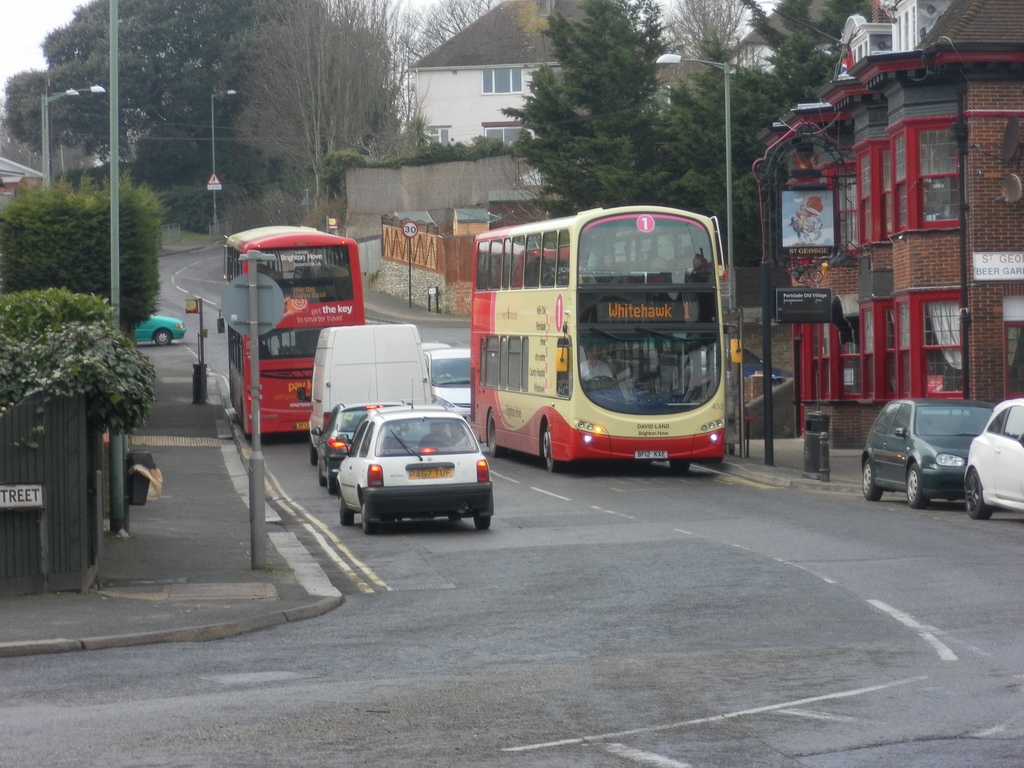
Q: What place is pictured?
A: It is a road.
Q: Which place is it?
A: It is a road.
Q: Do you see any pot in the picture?
A: No, there are no pots.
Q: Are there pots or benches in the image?
A: No, there are no pots or benches.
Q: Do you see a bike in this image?
A: No, there are no bikes.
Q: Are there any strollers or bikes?
A: No, there are no bikes or strollers.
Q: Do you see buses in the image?
A: Yes, there is a bus.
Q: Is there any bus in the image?
A: Yes, there is a bus.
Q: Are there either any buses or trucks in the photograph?
A: Yes, there is a bus.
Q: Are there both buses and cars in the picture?
A: Yes, there are both a bus and a car.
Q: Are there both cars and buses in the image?
A: Yes, there are both a bus and a car.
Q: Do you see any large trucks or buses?
A: Yes, there is a large bus.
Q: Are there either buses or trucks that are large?
A: Yes, the bus is large.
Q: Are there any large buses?
A: Yes, there is a large bus.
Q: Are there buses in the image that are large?
A: Yes, there is a bus that is large.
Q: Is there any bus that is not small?
A: Yes, there is a large bus.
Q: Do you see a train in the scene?
A: No, there are no trains.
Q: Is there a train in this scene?
A: No, there are no trains.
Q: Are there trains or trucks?
A: No, there are no trains or trucks.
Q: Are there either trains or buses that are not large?
A: No, there is a bus but it is large.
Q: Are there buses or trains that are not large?
A: No, there is a bus but it is large.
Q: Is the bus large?
A: Yes, the bus is large.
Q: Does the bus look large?
A: Yes, the bus is large.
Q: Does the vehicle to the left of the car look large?
A: Yes, the bus is large.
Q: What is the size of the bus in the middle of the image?
A: The bus is large.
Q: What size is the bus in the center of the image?
A: The bus is large.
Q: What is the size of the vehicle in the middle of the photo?
A: The bus is large.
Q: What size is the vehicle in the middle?
A: The bus is large.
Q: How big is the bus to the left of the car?
A: The bus is large.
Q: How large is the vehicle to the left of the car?
A: The bus is large.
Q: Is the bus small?
A: No, the bus is large.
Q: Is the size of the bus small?
A: No, the bus is large.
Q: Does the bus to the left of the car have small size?
A: No, the bus is large.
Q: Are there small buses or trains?
A: No, there is a bus but it is large.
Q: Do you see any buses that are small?
A: No, there is a bus but it is large.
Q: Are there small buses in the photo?
A: No, there is a bus but it is large.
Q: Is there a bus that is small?
A: No, there is a bus but it is large.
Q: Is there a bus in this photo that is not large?
A: No, there is a bus but it is large.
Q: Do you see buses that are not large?
A: No, there is a bus but it is large.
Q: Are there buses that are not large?
A: No, there is a bus but it is large.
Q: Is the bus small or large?
A: The bus is large.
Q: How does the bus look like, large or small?
A: The bus is large.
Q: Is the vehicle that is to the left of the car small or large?
A: The bus is large.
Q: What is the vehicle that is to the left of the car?
A: The vehicle is a bus.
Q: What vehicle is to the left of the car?
A: The vehicle is a bus.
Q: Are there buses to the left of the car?
A: Yes, there is a bus to the left of the car.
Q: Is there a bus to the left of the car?
A: Yes, there is a bus to the left of the car.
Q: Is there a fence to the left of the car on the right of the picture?
A: No, there is a bus to the left of the car.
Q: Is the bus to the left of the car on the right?
A: Yes, the bus is to the left of the car.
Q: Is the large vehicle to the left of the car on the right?
A: Yes, the bus is to the left of the car.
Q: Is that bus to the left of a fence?
A: No, the bus is to the left of the car.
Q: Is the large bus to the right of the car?
A: No, the bus is to the left of the car.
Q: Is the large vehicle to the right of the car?
A: No, the bus is to the left of the car.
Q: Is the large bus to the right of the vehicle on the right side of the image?
A: No, the bus is to the left of the car.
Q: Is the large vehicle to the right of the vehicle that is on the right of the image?
A: No, the bus is to the left of the car.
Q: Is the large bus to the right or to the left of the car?
A: The bus is to the left of the car.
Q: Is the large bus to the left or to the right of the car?
A: The bus is to the left of the car.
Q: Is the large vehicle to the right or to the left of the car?
A: The bus is to the left of the car.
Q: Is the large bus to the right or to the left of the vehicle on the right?
A: The bus is to the left of the car.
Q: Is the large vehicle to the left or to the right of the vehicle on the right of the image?
A: The bus is to the left of the car.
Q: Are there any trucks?
A: No, there are no trucks.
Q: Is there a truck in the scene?
A: No, there are no trucks.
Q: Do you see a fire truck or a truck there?
A: No, there are no trucks or fire trucks.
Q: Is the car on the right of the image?
A: Yes, the car is on the right of the image.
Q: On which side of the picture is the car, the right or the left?
A: The car is on the right of the image.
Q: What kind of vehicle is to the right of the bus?
A: The vehicle is a car.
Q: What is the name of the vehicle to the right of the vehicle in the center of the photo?
A: The vehicle is a car.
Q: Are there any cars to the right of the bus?
A: Yes, there is a car to the right of the bus.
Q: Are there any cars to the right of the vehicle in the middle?
A: Yes, there is a car to the right of the bus.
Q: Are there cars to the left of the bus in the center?
A: No, the car is to the right of the bus.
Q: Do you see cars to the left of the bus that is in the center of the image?
A: No, the car is to the right of the bus.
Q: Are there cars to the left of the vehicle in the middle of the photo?
A: No, the car is to the right of the bus.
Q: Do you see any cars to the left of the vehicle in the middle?
A: No, the car is to the right of the bus.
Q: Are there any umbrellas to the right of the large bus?
A: No, there is a car to the right of the bus.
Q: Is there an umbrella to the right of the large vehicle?
A: No, there is a car to the right of the bus.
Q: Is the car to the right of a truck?
A: No, the car is to the right of the bus.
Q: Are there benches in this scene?
A: No, there are no benches.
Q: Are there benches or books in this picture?
A: No, there are no benches or books.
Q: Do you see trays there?
A: No, there are no trays.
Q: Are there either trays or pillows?
A: No, there are no trays or pillows.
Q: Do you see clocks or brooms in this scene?
A: No, there are no clocks or brooms.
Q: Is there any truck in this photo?
A: No, there are no trucks.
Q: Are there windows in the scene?
A: Yes, there is a window.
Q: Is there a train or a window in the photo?
A: Yes, there is a window.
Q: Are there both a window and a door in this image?
A: No, there is a window but no doors.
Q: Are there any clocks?
A: No, there are no clocks.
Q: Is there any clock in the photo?
A: No, there are no clocks.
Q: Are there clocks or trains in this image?
A: No, there are no clocks or trains.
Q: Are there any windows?
A: Yes, there is a window.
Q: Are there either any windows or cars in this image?
A: Yes, there is a window.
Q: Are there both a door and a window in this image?
A: No, there is a window but no doors.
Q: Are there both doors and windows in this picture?
A: No, there is a window but no doors.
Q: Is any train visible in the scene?
A: No, there are no trains.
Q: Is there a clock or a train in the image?
A: No, there are no trains or clocks.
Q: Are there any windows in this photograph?
A: Yes, there is a window.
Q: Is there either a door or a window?
A: Yes, there is a window.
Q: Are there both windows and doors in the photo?
A: No, there is a window but no doors.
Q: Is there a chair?
A: No, there are no chairs.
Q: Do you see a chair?
A: No, there are no chairs.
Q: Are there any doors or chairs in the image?
A: No, there are no chairs or doors.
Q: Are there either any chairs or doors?
A: No, there are no chairs or doors.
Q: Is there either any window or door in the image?
A: Yes, there is a window.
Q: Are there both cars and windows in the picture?
A: Yes, there are both a window and a car.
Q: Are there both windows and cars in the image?
A: Yes, there are both a window and a car.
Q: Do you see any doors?
A: No, there are no doors.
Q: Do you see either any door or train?
A: No, there are no doors or trains.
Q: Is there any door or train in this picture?
A: No, there are no doors or trains.